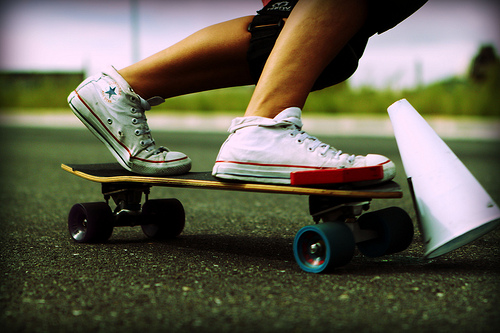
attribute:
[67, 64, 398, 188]
shoes — white, tennishoes, converse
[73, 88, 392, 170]
stripes — red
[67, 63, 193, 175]
shoe — red, white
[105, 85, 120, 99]
star — blue, logo star, converse logo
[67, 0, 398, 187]
person — skateboarding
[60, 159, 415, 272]
skateboard — black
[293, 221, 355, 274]
wheel — blue, red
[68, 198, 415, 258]
wheels — black, blue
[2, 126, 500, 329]
concrete — black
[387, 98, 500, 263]
cone — white, rubber cone, leaning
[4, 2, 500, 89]
sky — grey, overcast, clear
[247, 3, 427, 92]
shorts — dark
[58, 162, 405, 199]
trim — brown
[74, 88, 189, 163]
line — red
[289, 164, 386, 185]
object — red, square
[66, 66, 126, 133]
left foot heel — up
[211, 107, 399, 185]
foot — planted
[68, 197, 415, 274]
wheels — mismatched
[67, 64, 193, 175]
foot — leaning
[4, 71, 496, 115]
grass — green